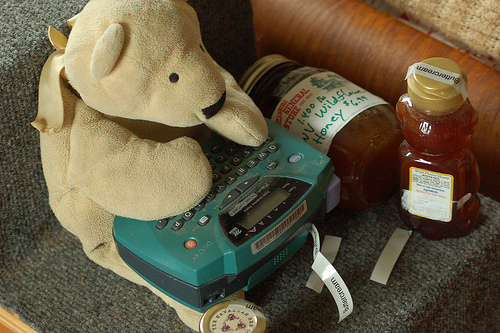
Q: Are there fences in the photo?
A: No, there are no fences.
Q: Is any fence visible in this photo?
A: No, there are no fences.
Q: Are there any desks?
A: No, there are no desks.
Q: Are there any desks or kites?
A: No, there are no desks or kites.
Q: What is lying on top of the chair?
A: The paper is lying on top of the chair.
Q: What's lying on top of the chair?
A: The paper is lying on top of the chair.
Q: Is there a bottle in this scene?
A: Yes, there is a bottle.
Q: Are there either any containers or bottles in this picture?
A: Yes, there is a bottle.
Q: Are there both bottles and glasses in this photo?
A: No, there is a bottle but no glasses.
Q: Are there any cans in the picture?
A: No, there are no cans.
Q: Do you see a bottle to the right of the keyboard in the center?
A: Yes, there is a bottle to the right of the keyboard.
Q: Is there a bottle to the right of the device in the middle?
A: Yes, there is a bottle to the right of the keyboard.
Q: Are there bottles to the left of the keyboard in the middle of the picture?
A: No, the bottle is to the right of the keyboard.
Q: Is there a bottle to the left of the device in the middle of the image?
A: No, the bottle is to the right of the keyboard.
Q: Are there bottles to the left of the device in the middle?
A: No, the bottle is to the right of the keyboard.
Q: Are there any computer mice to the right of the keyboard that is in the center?
A: No, there is a bottle to the right of the keyboard.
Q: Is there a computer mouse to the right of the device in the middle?
A: No, there is a bottle to the right of the keyboard.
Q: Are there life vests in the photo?
A: No, there are no life vests.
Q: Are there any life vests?
A: No, there are no life vests.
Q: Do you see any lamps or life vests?
A: No, there are no life vests or lamps.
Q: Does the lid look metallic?
A: Yes, the lid is metallic.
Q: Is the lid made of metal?
A: Yes, the lid is made of metal.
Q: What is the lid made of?
A: The lid is made of metal.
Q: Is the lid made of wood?
A: No, the lid is made of metal.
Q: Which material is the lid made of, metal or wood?
A: The lid is made of metal.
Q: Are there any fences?
A: No, there are no fences.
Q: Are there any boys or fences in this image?
A: No, there are no fences or boys.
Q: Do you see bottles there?
A: Yes, there is a bottle.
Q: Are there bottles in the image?
A: Yes, there is a bottle.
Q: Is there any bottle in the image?
A: Yes, there is a bottle.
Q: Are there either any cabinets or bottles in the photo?
A: Yes, there is a bottle.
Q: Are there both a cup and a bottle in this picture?
A: No, there is a bottle but no cups.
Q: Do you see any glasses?
A: No, there are no glasses.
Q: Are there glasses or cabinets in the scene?
A: No, there are no glasses or cabinets.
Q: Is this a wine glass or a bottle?
A: This is a bottle.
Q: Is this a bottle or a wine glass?
A: This is a bottle.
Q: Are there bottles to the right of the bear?
A: Yes, there is a bottle to the right of the bear.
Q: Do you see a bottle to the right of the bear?
A: Yes, there is a bottle to the right of the bear.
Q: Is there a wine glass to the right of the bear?
A: No, there is a bottle to the right of the bear.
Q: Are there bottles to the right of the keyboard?
A: Yes, there is a bottle to the right of the keyboard.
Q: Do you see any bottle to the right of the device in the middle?
A: Yes, there is a bottle to the right of the keyboard.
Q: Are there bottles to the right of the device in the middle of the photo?
A: Yes, there is a bottle to the right of the keyboard.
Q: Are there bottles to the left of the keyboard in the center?
A: No, the bottle is to the right of the keyboard.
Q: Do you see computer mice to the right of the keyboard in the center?
A: No, there is a bottle to the right of the keyboard.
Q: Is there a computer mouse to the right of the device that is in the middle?
A: No, there is a bottle to the right of the keyboard.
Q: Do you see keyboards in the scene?
A: Yes, there is a keyboard.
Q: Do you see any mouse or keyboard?
A: Yes, there is a keyboard.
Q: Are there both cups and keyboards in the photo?
A: No, there is a keyboard but no cups.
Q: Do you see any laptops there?
A: No, there are no laptops.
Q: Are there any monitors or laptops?
A: No, there are no laptops or monitors.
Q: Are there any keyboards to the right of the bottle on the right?
A: No, the keyboard is to the left of the bottle.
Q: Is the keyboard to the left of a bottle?
A: Yes, the keyboard is to the left of a bottle.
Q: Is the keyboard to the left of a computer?
A: No, the keyboard is to the left of a bottle.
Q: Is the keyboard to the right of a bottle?
A: No, the keyboard is to the left of a bottle.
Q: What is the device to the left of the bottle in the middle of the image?
A: The device is a keyboard.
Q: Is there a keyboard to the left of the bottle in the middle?
A: Yes, there is a keyboard to the left of the bottle.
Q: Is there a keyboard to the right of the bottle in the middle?
A: No, the keyboard is to the left of the bottle.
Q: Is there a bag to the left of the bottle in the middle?
A: No, there is a keyboard to the left of the bottle.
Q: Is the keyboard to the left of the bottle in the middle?
A: Yes, the keyboard is to the left of the bottle.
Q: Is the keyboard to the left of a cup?
A: No, the keyboard is to the left of the bottle.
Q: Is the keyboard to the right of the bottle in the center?
A: No, the keyboard is to the left of the bottle.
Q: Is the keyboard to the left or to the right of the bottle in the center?
A: The keyboard is to the left of the bottle.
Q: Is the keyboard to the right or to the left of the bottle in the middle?
A: The keyboard is to the left of the bottle.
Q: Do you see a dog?
A: No, there are no dogs.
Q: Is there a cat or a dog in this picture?
A: No, there are no dogs or cats.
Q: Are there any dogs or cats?
A: No, there are no dogs or cats.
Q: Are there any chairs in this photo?
A: Yes, there is a chair.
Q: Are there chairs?
A: Yes, there is a chair.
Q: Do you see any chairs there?
A: Yes, there is a chair.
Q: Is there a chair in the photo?
A: Yes, there is a chair.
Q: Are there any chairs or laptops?
A: Yes, there is a chair.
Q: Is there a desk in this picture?
A: No, there are no desks.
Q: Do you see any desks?
A: No, there are no desks.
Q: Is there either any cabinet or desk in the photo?
A: No, there are no desks or cabinets.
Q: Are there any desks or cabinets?
A: No, there are no desks or cabinets.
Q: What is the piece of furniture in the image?
A: The piece of furniture is a chair.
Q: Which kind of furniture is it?
A: The piece of furniture is a chair.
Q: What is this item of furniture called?
A: This is a chair.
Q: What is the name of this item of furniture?
A: This is a chair.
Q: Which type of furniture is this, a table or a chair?
A: This is a chair.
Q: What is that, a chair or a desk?
A: That is a chair.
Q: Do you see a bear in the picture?
A: Yes, there is a bear.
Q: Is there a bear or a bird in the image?
A: Yes, there is a bear.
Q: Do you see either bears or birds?
A: Yes, there is a bear.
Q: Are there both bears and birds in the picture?
A: No, there is a bear but no birds.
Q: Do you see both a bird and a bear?
A: No, there is a bear but no birds.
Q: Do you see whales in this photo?
A: No, there are no whales.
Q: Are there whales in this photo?
A: No, there are no whales.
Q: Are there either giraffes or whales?
A: No, there are no whales or giraffes.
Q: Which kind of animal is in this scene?
A: The animal is a bear.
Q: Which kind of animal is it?
A: The animal is a bear.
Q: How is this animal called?
A: This is a bear.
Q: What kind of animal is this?
A: This is a bear.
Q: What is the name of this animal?
A: This is a bear.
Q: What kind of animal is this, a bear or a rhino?
A: This is a bear.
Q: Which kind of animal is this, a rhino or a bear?
A: This is a bear.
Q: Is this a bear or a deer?
A: This is a bear.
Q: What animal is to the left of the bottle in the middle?
A: The animal is a bear.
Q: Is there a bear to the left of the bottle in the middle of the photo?
A: Yes, there is a bear to the left of the bottle.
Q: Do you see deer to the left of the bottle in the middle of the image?
A: No, there is a bear to the left of the bottle.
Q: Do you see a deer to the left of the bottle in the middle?
A: No, there is a bear to the left of the bottle.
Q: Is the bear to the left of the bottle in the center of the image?
A: Yes, the bear is to the left of the bottle.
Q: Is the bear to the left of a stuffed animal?
A: No, the bear is to the left of the bottle.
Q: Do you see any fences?
A: No, there are no fences.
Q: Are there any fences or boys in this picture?
A: No, there are no fences or boys.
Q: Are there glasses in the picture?
A: No, there are no glasses.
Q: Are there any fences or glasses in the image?
A: No, there are no glasses or fences.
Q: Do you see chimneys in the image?
A: No, there are no chimneys.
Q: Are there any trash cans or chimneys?
A: No, there are no chimneys or trash cans.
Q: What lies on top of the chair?
A: The paper lies on top of the chair.